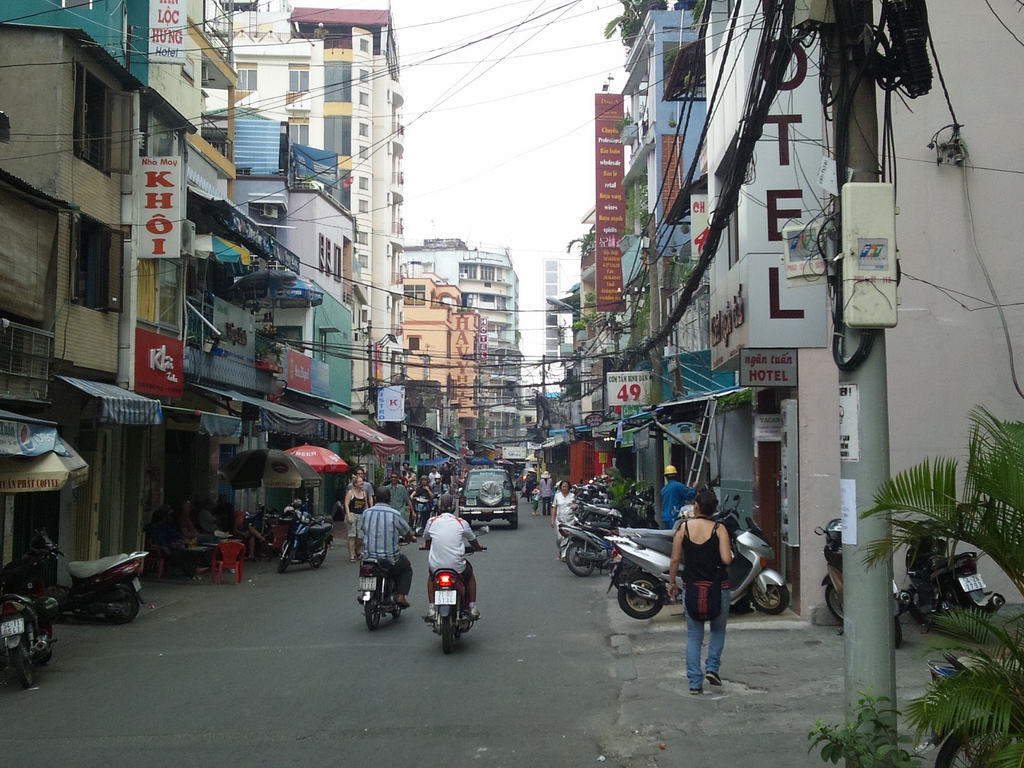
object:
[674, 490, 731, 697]
woman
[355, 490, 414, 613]
man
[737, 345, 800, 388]
hotelsign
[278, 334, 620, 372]
blackcables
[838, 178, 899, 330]
whitebox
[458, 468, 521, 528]
car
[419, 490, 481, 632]
man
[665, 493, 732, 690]
lady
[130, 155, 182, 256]
sign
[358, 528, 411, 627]
motorcycle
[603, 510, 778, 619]
motorcycle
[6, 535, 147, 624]
motorcycle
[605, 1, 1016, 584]
building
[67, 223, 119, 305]
window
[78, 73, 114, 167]
window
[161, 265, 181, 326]
window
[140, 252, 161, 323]
window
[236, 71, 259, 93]
window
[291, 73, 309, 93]
window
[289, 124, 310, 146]
window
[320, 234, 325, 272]
window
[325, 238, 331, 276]
window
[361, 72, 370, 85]
window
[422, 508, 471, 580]
shirt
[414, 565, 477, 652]
motorcycle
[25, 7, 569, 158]
cables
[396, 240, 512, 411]
buildings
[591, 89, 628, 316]
sign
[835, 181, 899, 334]
box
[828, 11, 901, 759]
pole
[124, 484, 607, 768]
road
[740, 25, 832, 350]
sign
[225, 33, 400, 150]
building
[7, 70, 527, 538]
building